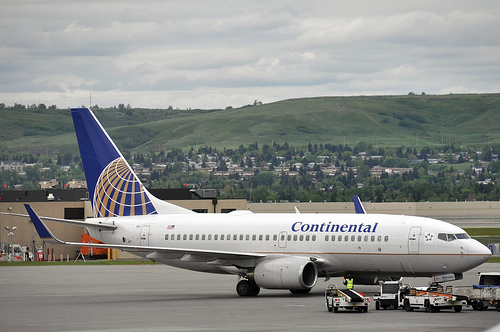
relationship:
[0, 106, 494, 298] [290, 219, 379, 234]
plane has logo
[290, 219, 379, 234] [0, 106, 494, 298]
logo on plane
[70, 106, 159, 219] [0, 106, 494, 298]
tail on plane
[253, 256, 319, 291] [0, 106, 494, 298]
engine on plane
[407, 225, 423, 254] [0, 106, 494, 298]
door on plane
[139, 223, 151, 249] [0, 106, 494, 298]
back door on plane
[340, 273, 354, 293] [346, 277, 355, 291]
crew in yellow vest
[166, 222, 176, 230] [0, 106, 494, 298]
flag on plane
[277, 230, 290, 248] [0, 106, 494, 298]
middle door on plane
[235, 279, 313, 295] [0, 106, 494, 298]
tires on plane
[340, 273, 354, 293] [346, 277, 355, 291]
crew wears yellow vest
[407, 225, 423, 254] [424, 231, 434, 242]
door near star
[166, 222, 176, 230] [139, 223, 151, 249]
flag near back door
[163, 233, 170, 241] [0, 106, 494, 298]
window on plane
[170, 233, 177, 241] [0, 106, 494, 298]
window on plane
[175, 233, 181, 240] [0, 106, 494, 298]
window on plane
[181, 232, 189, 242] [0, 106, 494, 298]
window on plane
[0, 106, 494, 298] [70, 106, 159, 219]
plane has tail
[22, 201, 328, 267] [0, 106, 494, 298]
wing on plane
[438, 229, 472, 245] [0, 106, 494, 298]
windshield on plane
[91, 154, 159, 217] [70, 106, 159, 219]
graphic on tail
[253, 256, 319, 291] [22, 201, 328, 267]
engine on wing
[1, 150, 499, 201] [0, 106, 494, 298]
town behind plane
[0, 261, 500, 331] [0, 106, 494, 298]
tarmac below plane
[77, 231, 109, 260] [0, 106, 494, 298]
tug behind plane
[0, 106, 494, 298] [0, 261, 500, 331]
plane on tarmac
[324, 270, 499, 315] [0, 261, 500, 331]
vehicles on tarmac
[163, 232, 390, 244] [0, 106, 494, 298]
windows on plane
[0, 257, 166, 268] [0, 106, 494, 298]
grass behind plane